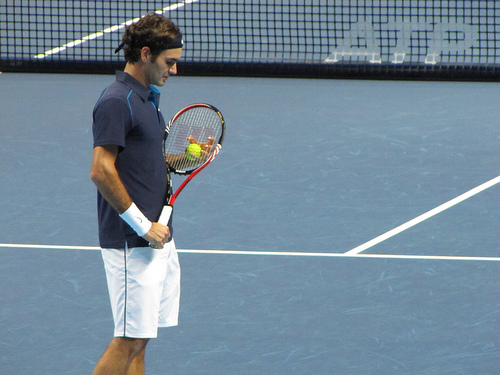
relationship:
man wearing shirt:
[90, 10, 188, 254] [88, 71, 187, 249]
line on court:
[0, 241, 500, 262] [1, 0, 500, 375]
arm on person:
[85, 150, 129, 207] [101, 10, 191, 103]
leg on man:
[88, 247, 165, 373] [90, 10, 216, 375]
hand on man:
[184, 133, 239, 181] [90, 10, 216, 375]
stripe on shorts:
[120, 242, 128, 337] [58, 207, 230, 344]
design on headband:
[179, 33, 185, 46] [112, 35, 191, 51]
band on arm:
[115, 199, 154, 241] [86, 95, 173, 250]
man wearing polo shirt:
[90, 10, 216, 375] [90, 69, 174, 248]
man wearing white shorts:
[90, 10, 216, 375] [101, 241, 176, 341]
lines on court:
[341, 159, 499, 255] [1, 3, 495, 372]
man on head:
[90, 10, 216, 375] [111, 13, 184, 84]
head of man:
[111, 13, 184, 84] [90, 10, 216, 375]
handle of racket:
[149, 194, 176, 248] [163, 103, 230, 240]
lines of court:
[194, 160, 492, 294] [1, 3, 495, 372]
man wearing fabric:
[90, 10, 216, 375] [115, 34, 183, 54]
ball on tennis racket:
[181, 135, 206, 164] [144, 95, 231, 245]